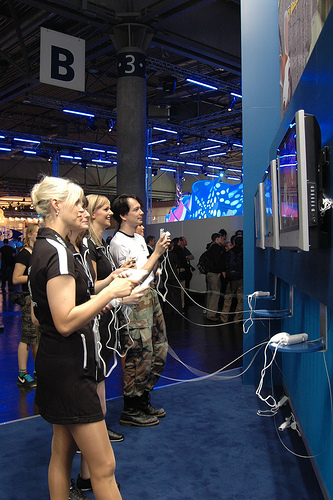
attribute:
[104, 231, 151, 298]
shirt — white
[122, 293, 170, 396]
pants — camo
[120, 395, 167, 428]
boots — black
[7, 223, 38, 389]
woman — standing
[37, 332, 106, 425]
skirt — black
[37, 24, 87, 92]
sign — white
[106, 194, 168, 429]
man — standing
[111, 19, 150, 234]
pole — cement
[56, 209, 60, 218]
earring — silver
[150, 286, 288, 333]
cord — white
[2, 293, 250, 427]
floor — blue, slippery, black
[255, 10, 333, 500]
wall — blue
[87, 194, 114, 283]
person — playing, standing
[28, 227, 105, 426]
dress — black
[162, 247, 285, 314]
cable — white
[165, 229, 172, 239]
joystick — white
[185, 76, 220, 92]
light — long, on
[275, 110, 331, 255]
screen — flat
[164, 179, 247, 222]
sign — curved